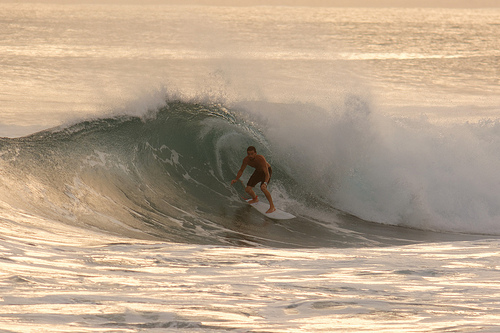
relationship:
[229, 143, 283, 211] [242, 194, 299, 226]
man on board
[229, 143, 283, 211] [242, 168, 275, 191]
man in shorts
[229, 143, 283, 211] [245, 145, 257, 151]
man with hair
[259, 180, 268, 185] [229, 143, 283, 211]
wristband on man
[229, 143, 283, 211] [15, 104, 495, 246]
man under wave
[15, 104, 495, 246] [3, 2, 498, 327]
wave in water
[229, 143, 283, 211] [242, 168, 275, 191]
man wearing shorts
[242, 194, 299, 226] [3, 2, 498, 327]
board in water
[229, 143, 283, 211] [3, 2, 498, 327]
man in water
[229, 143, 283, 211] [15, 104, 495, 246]
man in wave